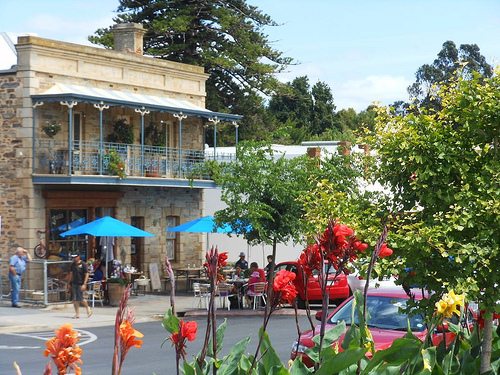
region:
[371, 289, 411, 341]
this is a car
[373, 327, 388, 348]
the car is red in color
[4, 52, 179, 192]
this is a building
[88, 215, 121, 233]
this is an umbrella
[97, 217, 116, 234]
the umbrella is blue in color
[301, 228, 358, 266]
the flowers are red in color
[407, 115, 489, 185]
the leaves are green in color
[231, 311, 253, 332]
this is a road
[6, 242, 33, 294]
the man is standing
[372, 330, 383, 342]
the car is parked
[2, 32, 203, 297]
building made of stone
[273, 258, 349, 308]
red car parked near building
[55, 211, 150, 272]
market umbrella in front of building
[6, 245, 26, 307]
man shielding eyes from sun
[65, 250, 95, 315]
man in cap walking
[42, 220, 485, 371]
flowers across street from building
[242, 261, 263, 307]
person in red sitting at table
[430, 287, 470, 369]
yellow gladiola like flowers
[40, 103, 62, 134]
hanging basket on balcony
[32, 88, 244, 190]
balcony of building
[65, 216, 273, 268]
blue umbrellas outside building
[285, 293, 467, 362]
red car across from building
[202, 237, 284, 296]
people under blue umbrella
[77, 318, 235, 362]
pavement is dark grey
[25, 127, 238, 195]
blue railing over umbrellas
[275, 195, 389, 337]
red flowers near car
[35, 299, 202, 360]
orange flowers near red flowers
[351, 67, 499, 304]
green tree near red car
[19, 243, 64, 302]
steel railing near blue umbrella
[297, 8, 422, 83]
sky is blue with few clouds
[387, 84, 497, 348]
Green leaves on a tree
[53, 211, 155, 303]
A blue table umbrella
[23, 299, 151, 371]
Two orange flowers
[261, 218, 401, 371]
Several red flowers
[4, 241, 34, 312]
A man with white hair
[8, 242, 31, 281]
A man wearing a blue shirt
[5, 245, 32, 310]
A man wearing blue pants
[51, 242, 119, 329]
A man walking on a sidewalk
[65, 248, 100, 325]
A man wearing shorts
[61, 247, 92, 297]
A man wearing a brown shirt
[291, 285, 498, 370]
red car parked by the flowers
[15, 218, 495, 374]
flowers growing by the street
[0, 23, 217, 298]
two story building next to the street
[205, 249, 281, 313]
group of people sitting out side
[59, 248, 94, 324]
man in a black shirt walking down the street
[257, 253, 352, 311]
red car parked by the group of people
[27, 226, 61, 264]
unicycle next to the building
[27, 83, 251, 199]
balcony attached to the building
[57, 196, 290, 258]
blue umbrellas for the tables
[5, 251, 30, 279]
blue shirt on the old man